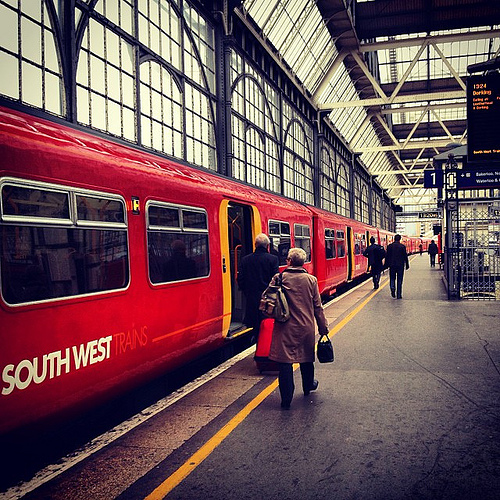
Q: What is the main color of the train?
A: Red.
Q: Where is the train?
A: Train tracks.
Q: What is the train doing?
A: Stopped.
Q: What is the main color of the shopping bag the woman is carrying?
A: Red.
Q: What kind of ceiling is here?
A: Glass.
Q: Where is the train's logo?
A: On te side of the train.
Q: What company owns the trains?
A: Southwest.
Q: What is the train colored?
A: Red.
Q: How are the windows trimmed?
A: In silver.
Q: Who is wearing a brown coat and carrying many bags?
A: An old lady.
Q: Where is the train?
A: In a station.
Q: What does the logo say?
A: South West Trains.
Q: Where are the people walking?
A: On the platform next to the train.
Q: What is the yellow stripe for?
A: Safety.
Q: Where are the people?
A: At a train station.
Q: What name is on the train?
A: South west trains.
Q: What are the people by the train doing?
A: Boarding the train.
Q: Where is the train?
A: In a train station.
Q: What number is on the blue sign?
A: 1.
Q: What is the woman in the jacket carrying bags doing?
A: Boarding a train.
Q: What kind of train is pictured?
A: A passenger train.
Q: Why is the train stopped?
A: So passengers can get on.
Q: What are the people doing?
A: Walking.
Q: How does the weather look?
A: Clear and calm.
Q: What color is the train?
A: Red.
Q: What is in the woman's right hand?
A: A purse.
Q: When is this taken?
A: During the day.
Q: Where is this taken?
A: A train station.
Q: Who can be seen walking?
A: People.